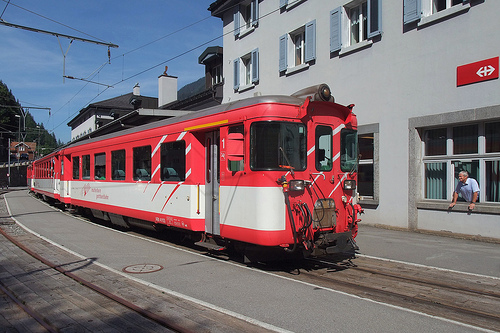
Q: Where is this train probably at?
A: Train station.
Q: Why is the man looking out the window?
A: Watch the train.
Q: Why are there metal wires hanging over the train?
A: Electrical current.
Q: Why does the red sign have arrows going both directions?
A: Shows trains possible directions.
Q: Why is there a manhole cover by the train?
A: Sewer entry.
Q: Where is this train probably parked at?
A: Train station.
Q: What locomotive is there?
A: Train.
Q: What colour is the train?
A: Red.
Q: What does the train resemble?
A: Streetcar.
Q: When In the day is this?
A: Afternoon.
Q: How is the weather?
A: Fair.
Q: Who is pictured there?
A: A man.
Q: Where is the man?
A: Window.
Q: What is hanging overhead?
A: Wires.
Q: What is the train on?
A: Tracks.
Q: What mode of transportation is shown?
A: Train.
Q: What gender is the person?
A: Male.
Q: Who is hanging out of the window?
A: The man.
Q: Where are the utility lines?
A: Over the train.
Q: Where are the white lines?
A: Beside the train.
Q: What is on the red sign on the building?
A: Arrows.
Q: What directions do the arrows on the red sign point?
A: Left and right.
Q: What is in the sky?
A: Clouds.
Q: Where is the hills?
A: Left side of the background.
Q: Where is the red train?
A: On tracks.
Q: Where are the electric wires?
A: In the air.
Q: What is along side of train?
A: White stripe.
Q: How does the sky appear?
A: Blue and clear.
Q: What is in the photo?
A: A train.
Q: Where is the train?
A: On the tracks.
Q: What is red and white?
A: The train.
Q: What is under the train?
A: Track.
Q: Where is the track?
A: Below the train.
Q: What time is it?
A: Afternoon.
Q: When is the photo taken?
A: Daytime.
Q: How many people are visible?
A: One.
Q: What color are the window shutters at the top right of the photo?
A: Blue.